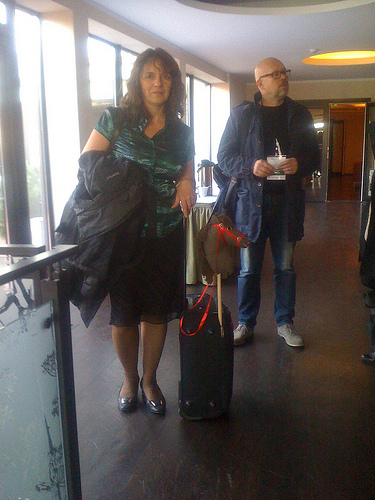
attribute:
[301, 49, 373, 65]
hole — large, round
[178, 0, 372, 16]
hole — large, round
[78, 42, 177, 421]
woman shirt — green 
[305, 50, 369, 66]
circle — large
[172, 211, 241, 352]
pony — stick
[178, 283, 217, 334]
ribbon — red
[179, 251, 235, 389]
suitcase — big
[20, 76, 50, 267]
panel — frosted, glass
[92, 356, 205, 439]
shoes — big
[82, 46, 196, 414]
lady — black 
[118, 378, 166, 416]
shoes — navy blue, professional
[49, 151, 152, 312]
jacket — black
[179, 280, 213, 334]
ribbon — red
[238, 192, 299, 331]
jeans — denim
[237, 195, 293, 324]
jeans — big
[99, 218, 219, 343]
skirt — pencil, black, chiffon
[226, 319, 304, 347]
white shoes — big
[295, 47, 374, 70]
ceiling light — big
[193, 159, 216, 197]
hotpot — steel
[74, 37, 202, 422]
woman — big